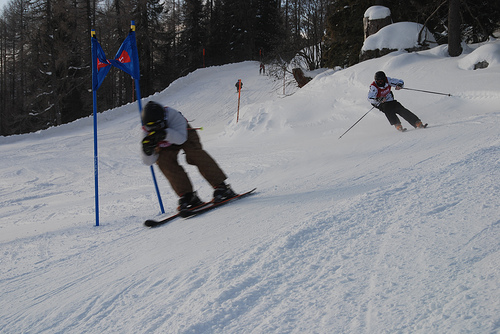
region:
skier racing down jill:
[136, 97, 246, 218]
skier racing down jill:
[355, 59, 420, 140]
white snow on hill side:
[36, 232, 121, 297]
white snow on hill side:
[135, 262, 225, 294]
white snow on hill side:
[283, 229, 341, 294]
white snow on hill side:
[263, 175, 355, 245]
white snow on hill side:
[378, 199, 452, 289]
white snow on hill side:
[18, 165, 70, 226]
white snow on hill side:
[265, 92, 322, 169]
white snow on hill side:
[302, 137, 357, 195]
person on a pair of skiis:
[120, 81, 265, 236]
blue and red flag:
[89, 22, 142, 97]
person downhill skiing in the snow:
[339, 60, 466, 167]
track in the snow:
[268, 228, 389, 303]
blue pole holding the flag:
[81, 100, 103, 230]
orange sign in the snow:
[232, 73, 245, 128]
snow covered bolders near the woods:
[345, 4, 430, 57]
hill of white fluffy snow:
[188, 62, 260, 75]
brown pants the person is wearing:
[149, 152, 226, 188]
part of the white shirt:
[167, 104, 187, 144]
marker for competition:
[88, 20, 165, 225]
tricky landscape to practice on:
[3, 30, 497, 332]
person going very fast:
[143, 101, 257, 228]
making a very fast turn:
[338, 70, 455, 142]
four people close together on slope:
[141, 58, 429, 215]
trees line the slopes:
[1, 1, 498, 131]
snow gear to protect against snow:
[141, 102, 170, 154]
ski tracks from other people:
[6, 144, 141, 331]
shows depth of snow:
[359, 4, 434, 53]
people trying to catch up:
[236, 60, 267, 90]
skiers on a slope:
[120, 65, 460, 230]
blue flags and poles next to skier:
[65, 20, 255, 230]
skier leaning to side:
[355, 65, 425, 130]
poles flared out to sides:
[335, 65, 455, 141]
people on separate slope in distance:
[230, 50, 270, 90]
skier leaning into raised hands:
[135, 90, 245, 225]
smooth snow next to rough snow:
[240, 115, 490, 265]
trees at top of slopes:
[5, 5, 355, 140]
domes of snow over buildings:
[355, 0, 440, 55]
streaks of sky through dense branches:
[0, 0, 315, 45]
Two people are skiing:
[140, 71, 452, 225]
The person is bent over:
[140, 101, 233, 209]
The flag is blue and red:
[90, 36, 113, 228]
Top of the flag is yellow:
[90, 29, 94, 36]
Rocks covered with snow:
[360, 6, 430, 56]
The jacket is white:
[141, 108, 186, 168]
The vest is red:
[370, 81, 391, 98]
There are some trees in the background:
[1, 0, 296, 63]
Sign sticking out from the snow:
[233, 77, 240, 122]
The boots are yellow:
[394, 121, 424, 131]